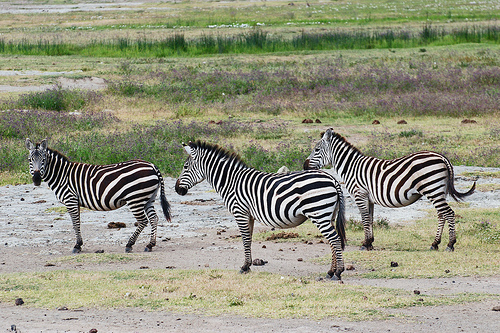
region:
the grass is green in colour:
[145, 22, 296, 62]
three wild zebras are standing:
[16, 77, 461, 317]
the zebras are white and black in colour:
[36, 111, 480, 281]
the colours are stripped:
[20, 118, 482, 314]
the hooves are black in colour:
[320, 258, 351, 283]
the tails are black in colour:
[331, 209, 349, 243]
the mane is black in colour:
[181, 141, 227, 160]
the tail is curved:
[411, 130, 480, 239]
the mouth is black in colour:
[168, 183, 192, 198]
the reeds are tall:
[146, 18, 252, 58]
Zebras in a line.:
[19, 116, 473, 301]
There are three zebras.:
[21, 113, 481, 278]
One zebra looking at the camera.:
[17, 135, 54, 200]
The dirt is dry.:
[43, 175, 373, 276]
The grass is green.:
[77, 18, 477, 48]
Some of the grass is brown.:
[102, 97, 482, 150]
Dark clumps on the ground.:
[100, 216, 288, 278]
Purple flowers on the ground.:
[292, 66, 491, 121]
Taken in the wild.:
[4, 5, 496, 331]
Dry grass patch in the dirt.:
[30, 268, 382, 331]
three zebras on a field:
[11, 111, 481, 296]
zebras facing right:
[19, 113, 479, 290]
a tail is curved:
[440, 150, 482, 205]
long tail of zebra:
[330, 178, 354, 254]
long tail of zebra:
[151, 171, 175, 226]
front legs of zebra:
[59, 206, 87, 260]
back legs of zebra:
[124, 208, 161, 249]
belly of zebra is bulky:
[247, 203, 307, 234]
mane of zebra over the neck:
[189, 135, 253, 173]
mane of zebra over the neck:
[324, 128, 366, 164]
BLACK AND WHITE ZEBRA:
[31, 123, 171, 258]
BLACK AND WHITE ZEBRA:
[202, 123, 312, 273]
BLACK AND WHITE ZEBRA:
[339, 74, 486, 266]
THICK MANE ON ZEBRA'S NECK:
[45, 143, 72, 168]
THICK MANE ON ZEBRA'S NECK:
[193, 137, 245, 160]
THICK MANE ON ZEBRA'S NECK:
[327, 129, 369, 154]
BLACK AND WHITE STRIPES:
[77, 175, 148, 216]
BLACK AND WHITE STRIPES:
[262, 174, 312, 214]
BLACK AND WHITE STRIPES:
[377, 156, 462, 230]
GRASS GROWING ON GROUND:
[230, 261, 291, 323]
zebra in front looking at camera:
[13, 135, 176, 260]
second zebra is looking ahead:
[166, 133, 353, 280]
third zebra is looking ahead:
[297, 118, 485, 268]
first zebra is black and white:
[22, 134, 178, 259]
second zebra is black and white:
[161, 128, 360, 285]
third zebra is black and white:
[296, 113, 481, 262]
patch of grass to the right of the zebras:
[0, 256, 467, 329]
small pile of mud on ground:
[258, 226, 303, 248]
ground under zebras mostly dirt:
[3, 158, 499, 331]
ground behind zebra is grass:
[0, 1, 497, 177]